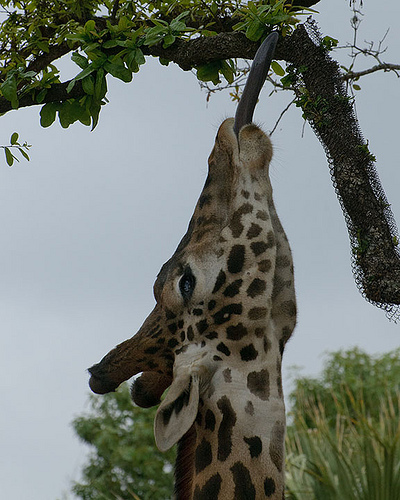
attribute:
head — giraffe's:
[67, 110, 309, 420]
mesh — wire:
[330, 106, 378, 218]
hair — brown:
[171, 430, 193, 492]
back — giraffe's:
[170, 343, 282, 498]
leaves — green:
[3, 1, 179, 123]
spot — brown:
[214, 394, 240, 466]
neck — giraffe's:
[163, 336, 292, 496]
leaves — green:
[48, 2, 300, 100]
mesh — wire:
[285, 29, 378, 211]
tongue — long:
[218, 27, 278, 125]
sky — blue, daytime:
[2, 125, 162, 232]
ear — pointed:
[141, 362, 217, 462]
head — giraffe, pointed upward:
[91, 113, 296, 363]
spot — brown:
[238, 365, 274, 402]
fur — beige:
[198, 400, 290, 491]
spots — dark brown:
[210, 202, 275, 471]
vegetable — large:
[219, 22, 290, 132]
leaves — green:
[0, 5, 320, 85]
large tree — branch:
[1, 2, 384, 324]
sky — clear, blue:
[3, 118, 205, 225]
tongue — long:
[212, 30, 291, 134]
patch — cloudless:
[111, 107, 196, 191]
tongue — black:
[232, 27, 278, 130]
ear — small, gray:
[146, 355, 219, 466]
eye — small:
[176, 263, 202, 307]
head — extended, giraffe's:
[57, 109, 297, 450]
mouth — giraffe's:
[192, 113, 281, 172]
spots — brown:
[222, 216, 282, 458]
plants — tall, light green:
[294, 337, 387, 497]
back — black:
[292, 19, 397, 307]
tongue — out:
[229, 26, 281, 127]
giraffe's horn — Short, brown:
[90, 327, 166, 409]